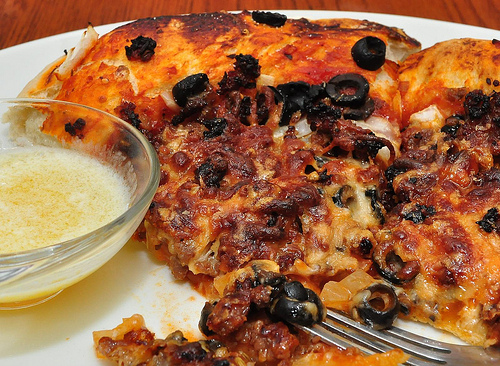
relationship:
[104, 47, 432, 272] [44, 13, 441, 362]
pieces of pizza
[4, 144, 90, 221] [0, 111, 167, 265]
butter in bowl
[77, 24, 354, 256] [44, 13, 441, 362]
slice of pizza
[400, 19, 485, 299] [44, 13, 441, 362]
slice of pizza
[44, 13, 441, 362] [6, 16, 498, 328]
pizza on table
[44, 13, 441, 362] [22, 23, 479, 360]
pizza on plate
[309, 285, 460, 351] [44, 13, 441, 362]
fork in pizza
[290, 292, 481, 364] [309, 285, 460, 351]
fork of fork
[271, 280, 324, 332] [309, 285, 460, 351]
olives touching fork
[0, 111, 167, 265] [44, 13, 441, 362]
bowl next to pizza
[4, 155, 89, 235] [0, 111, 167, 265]
butter in bowl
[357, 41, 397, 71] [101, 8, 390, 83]
olive on crust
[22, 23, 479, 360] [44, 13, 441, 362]
plate holding pizza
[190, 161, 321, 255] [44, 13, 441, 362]
cheese on pizza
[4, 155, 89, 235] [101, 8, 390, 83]
butter on crust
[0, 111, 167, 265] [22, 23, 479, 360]
bowl on plate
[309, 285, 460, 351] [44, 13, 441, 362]
fork on pizza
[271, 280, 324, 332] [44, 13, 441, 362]
olives on pizza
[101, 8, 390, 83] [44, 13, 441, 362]
crust of pizza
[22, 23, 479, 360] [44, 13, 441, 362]
plate with pizza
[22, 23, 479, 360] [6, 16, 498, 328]
plate on table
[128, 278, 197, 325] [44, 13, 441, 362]
grease of pizza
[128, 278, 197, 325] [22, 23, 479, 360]
grease on plate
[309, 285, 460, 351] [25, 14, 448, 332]
fork in food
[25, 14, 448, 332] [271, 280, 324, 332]
food has olives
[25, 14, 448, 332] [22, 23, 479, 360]
food on plate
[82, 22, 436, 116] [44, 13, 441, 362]
edge of pizza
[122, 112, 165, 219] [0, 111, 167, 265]
edge of bowl